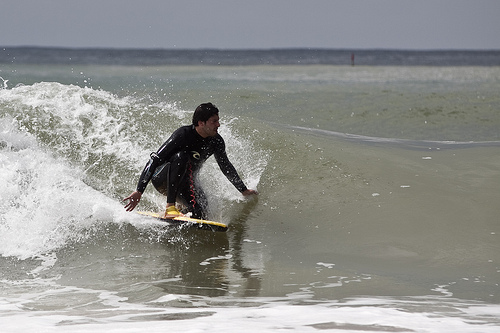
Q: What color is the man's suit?
A: Black.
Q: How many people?
A: One.